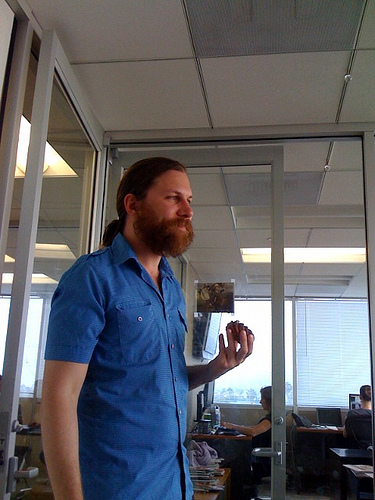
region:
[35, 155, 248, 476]
a man eating a doughnut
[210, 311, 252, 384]
a hand holding doughnut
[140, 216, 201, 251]
a bead covering cheeks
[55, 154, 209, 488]
a man wearing a blue shirt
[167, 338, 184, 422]
buttons on the shirt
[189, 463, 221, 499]
a stack of magazines on a table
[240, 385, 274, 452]
a woman typing at a computer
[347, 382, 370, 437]
a man looking at a computer screen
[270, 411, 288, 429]
a metal lock on the door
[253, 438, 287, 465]
a metal handle on the door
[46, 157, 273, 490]
man holding an object in his left hand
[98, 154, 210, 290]
man with a beard and mustache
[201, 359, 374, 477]
two women sitting at desks in an office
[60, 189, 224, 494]
man wearing a blue button down shirt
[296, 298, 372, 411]
white mini blinds covering window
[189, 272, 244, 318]
picture taped to office door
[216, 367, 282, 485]
woman sitting at desk typing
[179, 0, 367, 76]
white lights in drop down ceiling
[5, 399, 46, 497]
silver door handle and lock on office door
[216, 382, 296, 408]
trees seen outside office window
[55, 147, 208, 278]
Man beard and red hair entering office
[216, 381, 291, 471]
Woman sitting in chair doing work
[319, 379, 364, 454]
Woman sitting working on the computer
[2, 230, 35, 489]
Newly opened door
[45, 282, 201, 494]
Blue shirt with some buttons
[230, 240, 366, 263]
ceiling light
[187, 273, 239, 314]
photo pasted on the glass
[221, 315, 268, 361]
mini cake in the hand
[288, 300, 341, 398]
curtain in the window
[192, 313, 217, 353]
TV on the wall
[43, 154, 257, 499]
a man with red hair and beard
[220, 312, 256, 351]
a large brown pinecone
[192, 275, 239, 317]
a brown and grey image taped to a window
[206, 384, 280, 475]
a woman seated at a computer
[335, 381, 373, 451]
a woman using a computer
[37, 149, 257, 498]
a man in a blue shirt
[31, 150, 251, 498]
a man holding a pinecone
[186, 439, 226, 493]
a pile of papers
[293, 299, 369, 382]
a set of horizontal blinds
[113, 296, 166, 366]
a blue pocket with a silver button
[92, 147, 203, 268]
Facial hair full beard mustache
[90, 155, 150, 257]
Man thick ponytail back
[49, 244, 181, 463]
Shirt deep blue chest pocket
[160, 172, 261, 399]
Left hand doughnut eat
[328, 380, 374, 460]
Officer worker sits computer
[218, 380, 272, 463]
Woman hands computer keyboard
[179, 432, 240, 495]
Miscellaneous items stacked table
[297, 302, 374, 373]
White window blinds closed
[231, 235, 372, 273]
Fluorescent lighting panel overhead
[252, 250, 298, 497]
Sliding door office partition